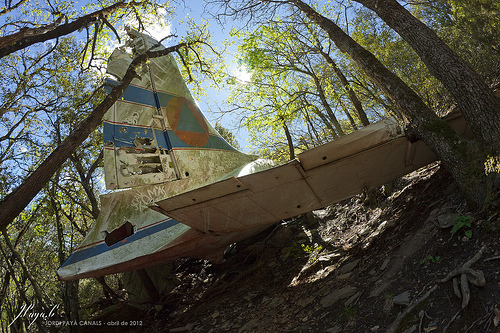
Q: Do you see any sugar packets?
A: No, there are no sugar packets.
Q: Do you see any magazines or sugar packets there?
A: No, there are no sugar packets or magazines.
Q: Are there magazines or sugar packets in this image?
A: No, there are no sugar packets or magazines.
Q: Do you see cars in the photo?
A: No, there are no cars.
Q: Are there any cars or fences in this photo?
A: No, there are no cars or fences.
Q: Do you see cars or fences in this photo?
A: No, there are no cars or fences.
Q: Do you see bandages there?
A: No, there are no bandages.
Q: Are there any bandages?
A: No, there are no bandages.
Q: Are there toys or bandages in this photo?
A: No, there are no bandages or toys.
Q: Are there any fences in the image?
A: No, there are no fences.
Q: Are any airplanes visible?
A: Yes, there is an airplane.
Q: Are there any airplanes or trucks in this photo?
A: Yes, there is an airplane.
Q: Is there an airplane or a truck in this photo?
A: Yes, there is an airplane.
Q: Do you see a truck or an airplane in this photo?
A: Yes, there is an airplane.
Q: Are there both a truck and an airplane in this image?
A: No, there is an airplane but no trucks.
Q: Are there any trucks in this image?
A: No, there are no trucks.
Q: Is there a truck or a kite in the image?
A: No, there are no trucks or kites.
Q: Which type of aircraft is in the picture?
A: The aircraft is an airplane.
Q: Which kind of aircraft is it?
A: The aircraft is an airplane.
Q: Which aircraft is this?
A: This is an airplane.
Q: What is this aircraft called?
A: This is an airplane.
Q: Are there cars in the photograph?
A: No, there are no cars.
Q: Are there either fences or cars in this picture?
A: No, there are no cars or fences.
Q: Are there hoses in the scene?
A: No, there are no hoses.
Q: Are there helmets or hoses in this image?
A: No, there are no hoses or helmets.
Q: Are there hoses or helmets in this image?
A: No, there are no hoses or helmets.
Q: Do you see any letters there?
A: Yes, there are letters.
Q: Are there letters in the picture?
A: Yes, there are letters.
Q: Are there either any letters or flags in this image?
A: Yes, there are letters.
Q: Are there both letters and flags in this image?
A: No, there are letters but no flags.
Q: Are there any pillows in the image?
A: No, there are no pillows.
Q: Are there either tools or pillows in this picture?
A: No, there are no pillows or tools.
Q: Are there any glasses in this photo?
A: No, there are no glasses.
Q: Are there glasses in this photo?
A: No, there are no glasses.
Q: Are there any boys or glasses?
A: No, there are no glasses or boys.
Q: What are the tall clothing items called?
A: The clothing items are trunks.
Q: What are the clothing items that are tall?
A: The clothing items are trunks.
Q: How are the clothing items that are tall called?
A: The clothing items are trunks.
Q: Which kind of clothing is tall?
A: The clothing is trunks.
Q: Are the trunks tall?
A: Yes, the trunks are tall.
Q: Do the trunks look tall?
A: Yes, the trunks are tall.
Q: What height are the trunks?
A: The trunks are tall.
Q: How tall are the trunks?
A: The trunks are tall.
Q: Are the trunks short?
A: No, the trunks are tall.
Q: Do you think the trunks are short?
A: No, the trunks are tall.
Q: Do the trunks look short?
A: No, the trunks are tall.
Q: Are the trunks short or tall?
A: The trunks are tall.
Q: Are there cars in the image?
A: No, there are no cars.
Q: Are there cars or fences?
A: No, there are no cars or fences.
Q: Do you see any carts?
A: No, there are no carts.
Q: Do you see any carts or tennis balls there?
A: No, there are no carts or tennis balls.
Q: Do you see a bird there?
A: No, there are no birds.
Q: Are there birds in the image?
A: No, there are no birds.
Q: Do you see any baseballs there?
A: No, there are no baseballs.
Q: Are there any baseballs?
A: No, there are no baseballs.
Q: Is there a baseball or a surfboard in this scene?
A: No, there are no baseballs or surfboards.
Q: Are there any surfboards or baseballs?
A: No, there are no baseballs or surfboards.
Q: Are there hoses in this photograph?
A: No, there are no hoses.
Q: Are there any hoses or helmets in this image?
A: No, there are no hoses or helmets.